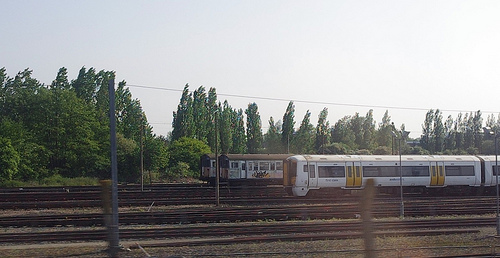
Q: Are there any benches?
A: No, there are no benches.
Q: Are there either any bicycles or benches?
A: No, there are no benches or bicycles.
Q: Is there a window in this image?
A: Yes, there is a window.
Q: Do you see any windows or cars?
A: Yes, there is a window.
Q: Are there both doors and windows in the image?
A: Yes, there are both a window and a door.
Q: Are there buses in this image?
A: No, there are no buses.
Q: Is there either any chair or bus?
A: No, there are no buses or chairs.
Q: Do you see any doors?
A: Yes, there is a door.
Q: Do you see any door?
A: Yes, there is a door.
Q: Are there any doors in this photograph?
A: Yes, there is a door.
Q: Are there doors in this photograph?
A: Yes, there is a door.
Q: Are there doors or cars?
A: Yes, there is a door.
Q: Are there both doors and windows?
A: Yes, there are both a door and a window.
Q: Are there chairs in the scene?
A: No, there are no chairs.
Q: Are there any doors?
A: Yes, there are doors.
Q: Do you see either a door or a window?
A: Yes, there are doors.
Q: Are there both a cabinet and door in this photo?
A: No, there are doors but no cabinets.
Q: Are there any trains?
A: Yes, there is a train.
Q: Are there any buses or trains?
A: Yes, there is a train.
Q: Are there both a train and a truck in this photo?
A: No, there is a train but no trucks.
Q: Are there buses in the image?
A: No, there are no buses.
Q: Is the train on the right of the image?
A: Yes, the train is on the right of the image.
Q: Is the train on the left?
A: No, the train is on the right of the image.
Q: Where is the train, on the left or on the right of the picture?
A: The train is on the right of the image.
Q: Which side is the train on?
A: The train is on the right of the image.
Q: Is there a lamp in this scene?
A: No, there are no lamps.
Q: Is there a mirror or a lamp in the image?
A: No, there are no lamps or mirrors.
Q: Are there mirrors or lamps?
A: No, there are no lamps or mirrors.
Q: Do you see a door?
A: Yes, there are doors.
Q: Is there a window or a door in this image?
A: Yes, there are doors.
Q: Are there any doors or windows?
A: Yes, there are doors.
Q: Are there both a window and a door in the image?
A: Yes, there are both a door and a window.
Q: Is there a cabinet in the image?
A: No, there are no cabinets.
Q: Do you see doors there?
A: Yes, there are doors.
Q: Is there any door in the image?
A: Yes, there are doors.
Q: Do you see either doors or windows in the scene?
A: Yes, there are doors.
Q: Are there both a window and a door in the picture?
A: Yes, there are both a door and a window.